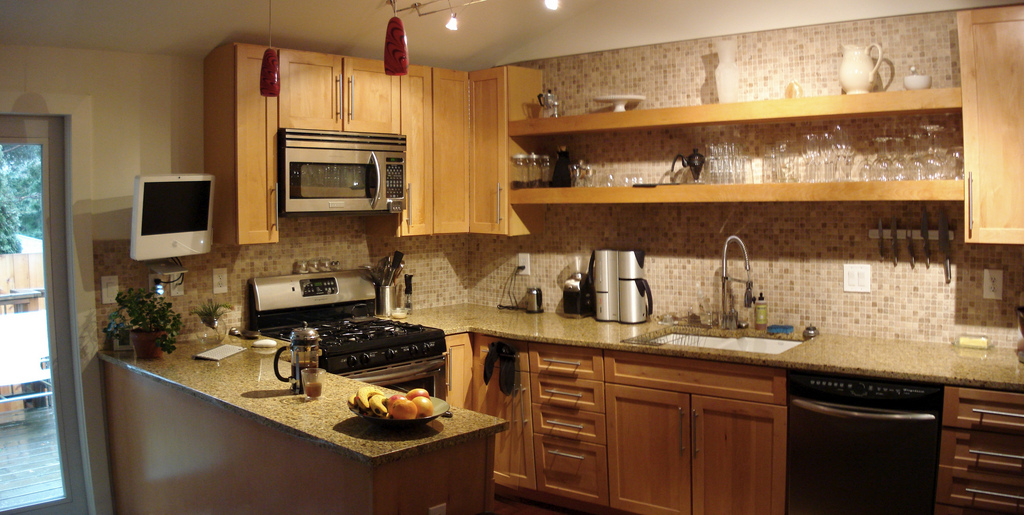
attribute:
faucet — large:
[714, 230, 756, 330]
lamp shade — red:
[379, 16, 410, 81]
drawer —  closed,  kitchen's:
[532, 351, 600, 395]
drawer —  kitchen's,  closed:
[527, 348, 601, 387]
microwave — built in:
[273, 122, 405, 222]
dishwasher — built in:
[768, 357, 924, 509]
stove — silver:
[245, 262, 453, 401]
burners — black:
[274, 317, 452, 380]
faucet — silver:
[709, 227, 772, 297]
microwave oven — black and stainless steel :
[315, 205, 398, 206]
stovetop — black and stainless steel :
[330, 287, 372, 348]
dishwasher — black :
[786, 311, 938, 504]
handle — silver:
[776, 405, 937, 427]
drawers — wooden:
[229, 233, 450, 246]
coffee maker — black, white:
[553, 233, 660, 329]